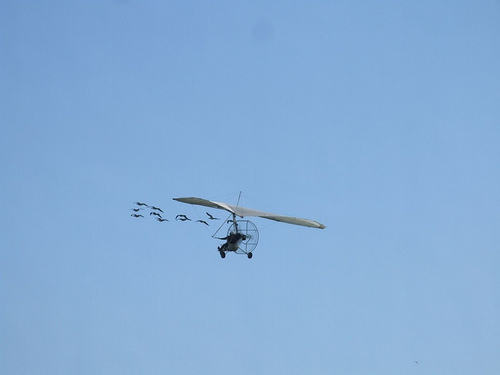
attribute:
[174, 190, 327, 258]
plane — flying, small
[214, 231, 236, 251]
man — flying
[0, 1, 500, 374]
sky — blue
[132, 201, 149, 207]
bird — flying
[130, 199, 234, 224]
birds — flying, black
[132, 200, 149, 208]
wings — dark grey